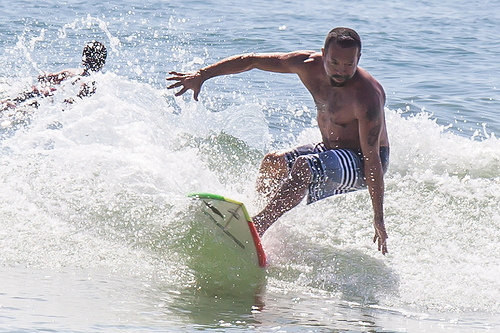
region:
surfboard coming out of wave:
[184, 191, 269, 268]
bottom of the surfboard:
[181, 199, 271, 284]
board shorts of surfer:
[278, 142, 378, 204]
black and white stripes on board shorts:
[283, 140, 366, 197]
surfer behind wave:
[30, 31, 112, 101]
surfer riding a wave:
[158, 33, 410, 285]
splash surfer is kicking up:
[18, 15, 255, 182]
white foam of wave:
[12, 120, 499, 224]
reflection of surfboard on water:
[160, 269, 252, 331]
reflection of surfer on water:
[288, 291, 408, 331]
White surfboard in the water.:
[172, 185, 272, 298]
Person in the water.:
[7, 33, 107, 134]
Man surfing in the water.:
[169, 25, 391, 277]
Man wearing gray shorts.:
[271, 25, 391, 201]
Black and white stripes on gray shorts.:
[329, 145, 359, 195]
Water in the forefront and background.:
[3, 3, 495, 330]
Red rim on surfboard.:
[246, 216, 266, 268]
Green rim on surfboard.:
[184, 189, 224, 204]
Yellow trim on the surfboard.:
[223, 195, 253, 223]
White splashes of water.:
[383, 110, 498, 174]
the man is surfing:
[158, 28, 418, 302]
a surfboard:
[189, 178, 272, 258]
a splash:
[33, 124, 163, 191]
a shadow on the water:
[280, 225, 386, 306]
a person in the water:
[41, 21, 117, 99]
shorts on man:
[304, 150, 361, 195]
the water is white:
[98, 75, 180, 171]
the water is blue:
[385, 15, 481, 94]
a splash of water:
[107, 15, 165, 67]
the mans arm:
[351, 105, 406, 248]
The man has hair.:
[293, 23, 397, 120]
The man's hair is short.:
[303, 19, 430, 132]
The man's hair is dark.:
[296, 15, 396, 112]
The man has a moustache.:
[300, 10, 381, 128]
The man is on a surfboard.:
[146, 12, 414, 316]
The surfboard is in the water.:
[147, 25, 404, 295]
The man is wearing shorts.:
[144, 20, 412, 297]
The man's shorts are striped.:
[158, 19, 407, 312]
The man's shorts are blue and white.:
[161, 18, 412, 312]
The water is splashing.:
[1, 5, 498, 329]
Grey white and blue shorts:
[282, 143, 361, 198]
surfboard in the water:
[193, 194, 270, 304]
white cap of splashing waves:
[415, 135, 487, 290]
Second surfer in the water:
[5, 31, 120, 141]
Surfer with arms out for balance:
[140, 20, 425, 247]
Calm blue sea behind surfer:
[392, 18, 470, 79]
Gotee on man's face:
[323, 71, 355, 87]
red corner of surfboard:
[241, 219, 273, 272]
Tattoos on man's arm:
[361, 97, 386, 153]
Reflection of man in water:
[335, 280, 391, 331]